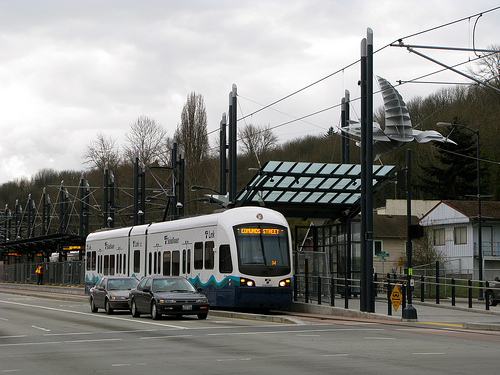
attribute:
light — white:
[246, 279, 252, 287]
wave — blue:
[186, 273, 240, 290]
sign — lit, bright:
[238, 214, 295, 249]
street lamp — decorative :
[336, 74, 458, 318]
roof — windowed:
[236, 159, 398, 204]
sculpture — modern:
[339, 72, 462, 169]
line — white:
[5, 293, 187, 343]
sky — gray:
[0, 0, 499, 185]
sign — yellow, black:
[390, 283, 404, 310]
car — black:
[128, 271, 228, 343]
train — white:
[82, 204, 296, 316]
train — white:
[42, 174, 386, 322]